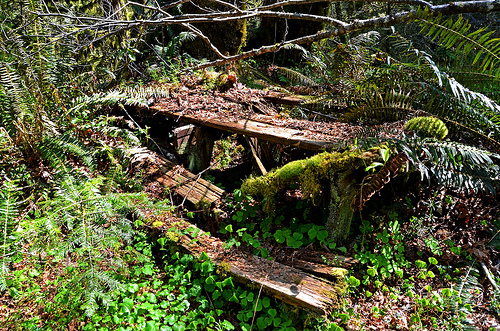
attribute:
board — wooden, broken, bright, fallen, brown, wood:
[76, 72, 413, 158]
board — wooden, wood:
[85, 141, 363, 317]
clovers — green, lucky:
[68, 188, 406, 331]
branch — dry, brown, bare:
[25, 0, 499, 73]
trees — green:
[0, 2, 500, 180]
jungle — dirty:
[1, 2, 499, 330]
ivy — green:
[440, 264, 484, 322]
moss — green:
[243, 149, 364, 193]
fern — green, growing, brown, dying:
[0, 31, 162, 180]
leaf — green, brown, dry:
[409, 7, 500, 78]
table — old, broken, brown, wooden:
[76, 73, 415, 313]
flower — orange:
[227, 71, 237, 84]